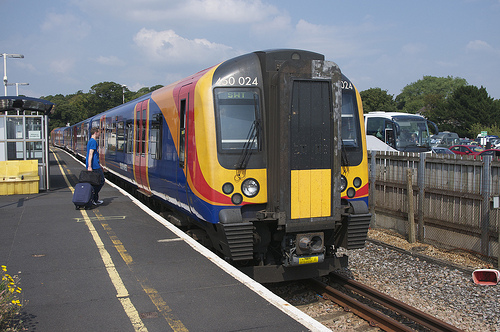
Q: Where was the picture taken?
A: It was taken at the station.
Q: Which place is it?
A: It is a station.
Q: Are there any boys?
A: No, there are no boys.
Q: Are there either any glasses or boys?
A: No, there are no boys or glasses.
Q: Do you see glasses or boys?
A: No, there are no boys or glasses.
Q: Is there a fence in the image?
A: Yes, there is a fence.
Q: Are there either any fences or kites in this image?
A: Yes, there is a fence.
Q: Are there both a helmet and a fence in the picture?
A: No, there is a fence but no helmets.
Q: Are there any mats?
A: No, there are no mats.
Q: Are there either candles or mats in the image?
A: No, there are no mats or candles.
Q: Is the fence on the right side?
A: Yes, the fence is on the right of the image.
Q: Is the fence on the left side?
A: No, the fence is on the right of the image.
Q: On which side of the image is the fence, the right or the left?
A: The fence is on the right of the image.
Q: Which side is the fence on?
A: The fence is on the right of the image.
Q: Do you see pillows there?
A: No, there are no pillows.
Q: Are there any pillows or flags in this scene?
A: No, there are no pillows or flags.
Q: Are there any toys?
A: No, there are no toys.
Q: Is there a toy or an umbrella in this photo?
A: No, there are no toys or umbrellas.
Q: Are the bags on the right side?
A: No, the bags are on the left of the image.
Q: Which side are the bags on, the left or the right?
A: The bags are on the left of the image.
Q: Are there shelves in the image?
A: No, there are no shelves.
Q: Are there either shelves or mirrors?
A: No, there are no shelves or mirrors.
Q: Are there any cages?
A: No, there are no cages.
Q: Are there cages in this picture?
A: No, there are no cages.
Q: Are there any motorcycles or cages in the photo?
A: No, there are no cages or motorcycles.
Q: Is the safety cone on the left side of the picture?
A: No, the safety cone is on the right of the image.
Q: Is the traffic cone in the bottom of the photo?
A: Yes, the traffic cone is in the bottom of the image.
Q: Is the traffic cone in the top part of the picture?
A: No, the traffic cone is in the bottom of the image.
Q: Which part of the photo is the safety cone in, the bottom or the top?
A: The safety cone is in the bottom of the image.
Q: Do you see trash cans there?
A: No, there are no trash cans.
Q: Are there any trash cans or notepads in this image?
A: No, there are no trash cans or notepads.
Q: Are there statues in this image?
A: No, there are no statues.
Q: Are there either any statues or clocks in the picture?
A: No, there are no statues or clocks.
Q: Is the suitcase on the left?
A: Yes, the suitcase is on the left of the image.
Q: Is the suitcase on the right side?
A: No, the suitcase is on the left of the image.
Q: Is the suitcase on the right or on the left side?
A: The suitcase is on the left of the image.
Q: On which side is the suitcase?
A: The suitcase is on the left of the image.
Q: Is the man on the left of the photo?
A: Yes, the man is on the left of the image.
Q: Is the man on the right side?
A: No, the man is on the left of the image.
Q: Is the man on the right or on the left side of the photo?
A: The man is on the left of the image.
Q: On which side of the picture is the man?
A: The man is on the left of the image.